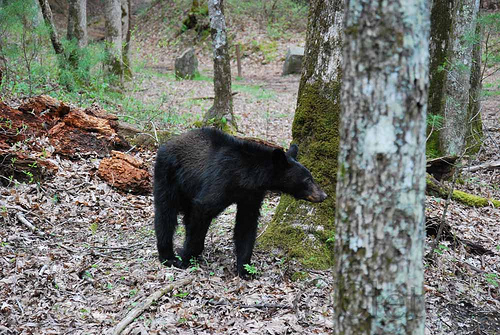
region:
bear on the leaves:
[149, 116, 330, 271]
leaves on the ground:
[17, 193, 323, 330]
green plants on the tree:
[286, 88, 338, 240]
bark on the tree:
[343, 127, 397, 297]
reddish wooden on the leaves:
[8, 85, 148, 202]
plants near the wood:
[6, 11, 140, 103]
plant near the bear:
[240, 257, 265, 284]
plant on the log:
[447, 178, 497, 211]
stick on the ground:
[100, 279, 199, 330]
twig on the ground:
[8, 202, 42, 241]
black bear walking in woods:
[151, 127, 328, 276]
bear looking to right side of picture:
[154, 126, 329, 281]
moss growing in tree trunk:
[261, 79, 341, 266]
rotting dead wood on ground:
[3, 94, 152, 193]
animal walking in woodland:
[8, 6, 484, 313]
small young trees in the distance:
[0, 0, 127, 98]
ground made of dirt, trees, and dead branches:
[14, 202, 144, 332]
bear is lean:
[152, 128, 329, 279]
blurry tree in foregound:
[331, 4, 431, 333]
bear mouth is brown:
[282, 149, 328, 205]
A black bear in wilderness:
[154, 128, 327, 271]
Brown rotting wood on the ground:
[0, 96, 146, 193]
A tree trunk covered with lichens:
[335, 3, 427, 333]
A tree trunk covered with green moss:
[265, 1, 337, 249]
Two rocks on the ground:
[175, 45, 304, 75]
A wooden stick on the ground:
[113, 273, 192, 332]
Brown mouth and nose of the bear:
[310, 181, 327, 203]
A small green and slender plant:
[431, 10, 498, 241]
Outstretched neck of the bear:
[263, 144, 287, 192]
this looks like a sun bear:
[137, 113, 344, 279]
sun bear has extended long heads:
[258, 140, 354, 224]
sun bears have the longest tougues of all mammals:
[273, 135, 331, 214]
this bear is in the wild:
[68, 84, 434, 291]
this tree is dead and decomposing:
[16, 89, 182, 196]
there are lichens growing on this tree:
[279, 70, 391, 292]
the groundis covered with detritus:
[22, 209, 302, 330]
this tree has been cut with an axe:
[148, 31, 223, 95]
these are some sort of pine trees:
[389, 13, 495, 190]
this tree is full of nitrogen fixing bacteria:
[15, 83, 148, 203]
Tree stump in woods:
[172, 46, 200, 80]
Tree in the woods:
[202, 1, 237, 131]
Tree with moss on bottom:
[254, 1, 351, 276]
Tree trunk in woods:
[334, 0, 428, 334]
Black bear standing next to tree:
[152, 126, 327, 280]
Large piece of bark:
[95, 148, 151, 195]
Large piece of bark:
[1, 146, 58, 187]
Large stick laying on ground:
[106, 276, 193, 334]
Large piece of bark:
[0, 92, 63, 145]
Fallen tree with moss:
[423, 168, 498, 211]